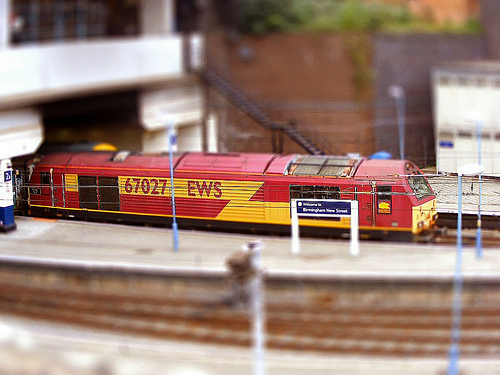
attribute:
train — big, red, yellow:
[9, 139, 444, 246]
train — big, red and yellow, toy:
[0, 146, 439, 236]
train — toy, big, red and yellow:
[8, 150, 450, 245]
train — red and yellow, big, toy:
[25, 149, 438, 241]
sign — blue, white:
[289, 191, 356, 224]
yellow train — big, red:
[193, 201, 368, 272]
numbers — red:
[120, 169, 172, 196]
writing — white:
[296, 199, 350, 215]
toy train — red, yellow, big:
[24, 133, 450, 254]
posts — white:
[282, 192, 365, 257]